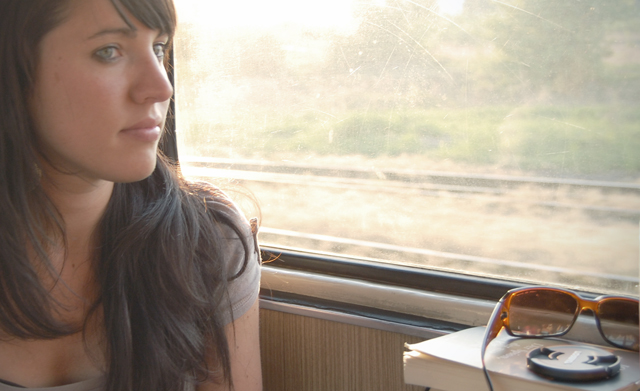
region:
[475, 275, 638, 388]
Pair of brown sunglasses.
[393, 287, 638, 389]
Book with glasses on top.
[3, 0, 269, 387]
Young lady with long dark hair.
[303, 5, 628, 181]
Green trees and bushes outside window.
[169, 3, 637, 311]
Window with sun shining through.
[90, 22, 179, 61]
The young lady's eyes.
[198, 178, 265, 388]
Left arm of the lady.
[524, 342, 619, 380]
Coffee mug spill proof lid.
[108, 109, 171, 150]
The woman's closed lips.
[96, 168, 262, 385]
Dark hair across shoulder.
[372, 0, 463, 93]
the window has scratches on it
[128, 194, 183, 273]
her hair is black in color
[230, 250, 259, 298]
the shirt is gray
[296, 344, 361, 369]
the wall is brown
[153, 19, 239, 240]
she is sitting by the window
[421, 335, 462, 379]
the book is white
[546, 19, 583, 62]
the leaves are green on the tree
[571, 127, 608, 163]
the grass is green in color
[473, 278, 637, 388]
Sunglasses on the book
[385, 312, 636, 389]
Book beside the window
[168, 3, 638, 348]
Window on the train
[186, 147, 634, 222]
railroad tracks on the ground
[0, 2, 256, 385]
Girl sitting on the train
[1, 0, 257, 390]
Long dark brown hair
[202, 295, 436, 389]
Tan coloring on the train wall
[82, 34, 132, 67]
Green colored eye on the girl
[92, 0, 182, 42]
Bangs on the forehead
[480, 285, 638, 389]
the sunglasses are brown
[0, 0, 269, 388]
the hair is brown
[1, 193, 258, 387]
the shirt is light brown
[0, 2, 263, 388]
the girl wearing the light brown top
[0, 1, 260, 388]
the girl has two eyes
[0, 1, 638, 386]
the girl sitting next to the window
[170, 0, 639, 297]
the window is large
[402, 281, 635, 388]
the book under the sunglasses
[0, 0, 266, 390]
the girl has blue-green eyes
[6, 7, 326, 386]
girl sitting by a window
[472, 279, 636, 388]
sunglasses sitting on top of a book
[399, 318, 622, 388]
a paperback book laying down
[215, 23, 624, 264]
window of a train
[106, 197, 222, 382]
long brown hair on the girl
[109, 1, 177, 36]
girl has short brown bangs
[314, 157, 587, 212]
train tracks outside the window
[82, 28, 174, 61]
girl has green eyes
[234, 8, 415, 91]
sun shining outside the window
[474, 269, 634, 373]
amber framed sunglasses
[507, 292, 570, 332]
dark lens on sunglasses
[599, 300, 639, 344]
dark lens on sunglasses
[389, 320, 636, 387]
large white book under sunglasses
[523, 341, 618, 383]
round disc on book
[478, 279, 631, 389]
sunglasses on white book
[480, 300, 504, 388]
amber colored arm on sunglasses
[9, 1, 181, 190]
woman looking out window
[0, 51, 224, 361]
girl has brown hair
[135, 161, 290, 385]
girl has grey shirt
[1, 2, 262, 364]
girl has long hair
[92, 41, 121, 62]
eye belongs to human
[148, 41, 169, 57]
eye belongs to human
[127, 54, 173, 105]
nose belongs to human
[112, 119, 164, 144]
mouth belongs to human